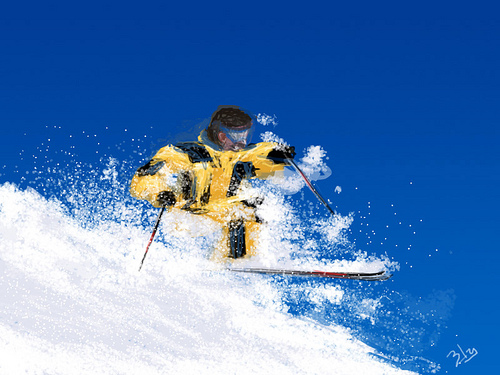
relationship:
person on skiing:
[132, 101, 383, 315] [138, 171, 388, 299]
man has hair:
[129, 87, 299, 296] [208, 102, 252, 146]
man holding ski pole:
[129, 87, 299, 296] [269, 132, 359, 234]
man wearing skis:
[129, 87, 299, 296] [172, 262, 393, 282]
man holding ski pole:
[129, 87, 299, 296] [271, 138, 345, 223]